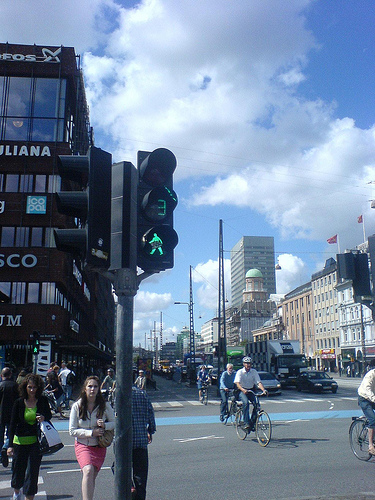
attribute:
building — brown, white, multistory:
[0, 40, 118, 382]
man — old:
[234, 356, 266, 439]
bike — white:
[232, 401, 273, 448]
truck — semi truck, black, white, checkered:
[227, 347, 242, 365]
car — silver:
[254, 367, 281, 395]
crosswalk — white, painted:
[0, 471, 38, 498]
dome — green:
[237, 267, 267, 279]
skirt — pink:
[78, 449, 104, 462]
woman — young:
[67, 373, 117, 498]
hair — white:
[223, 360, 233, 372]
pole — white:
[334, 231, 341, 254]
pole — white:
[360, 212, 363, 244]